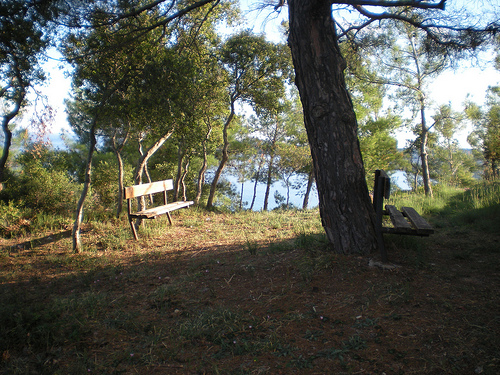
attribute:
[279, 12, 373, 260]
tree — crooked, bare, tall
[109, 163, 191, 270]
seat — wood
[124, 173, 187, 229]
bench — wood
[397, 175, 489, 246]
grass — green, tall, sparse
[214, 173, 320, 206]
water — in distance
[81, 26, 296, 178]
trees — green, short, small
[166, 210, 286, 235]
sand — brown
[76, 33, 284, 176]
leaves — green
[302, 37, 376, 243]
trunk — large, wooden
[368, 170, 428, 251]
bench — wooden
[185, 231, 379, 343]
path — walkable, shadowed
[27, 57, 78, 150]
sky — blue, bright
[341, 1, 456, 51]
branch — long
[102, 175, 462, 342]
ground — sloped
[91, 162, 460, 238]
benches — wooden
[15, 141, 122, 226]
shrubs — green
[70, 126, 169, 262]
trunk — curved